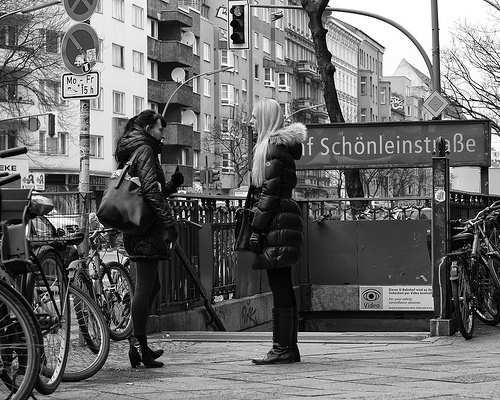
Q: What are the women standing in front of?
A: Entrance to the subway.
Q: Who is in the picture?
A: Two women.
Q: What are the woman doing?
A: Talking.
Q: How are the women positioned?
A: Across from one another.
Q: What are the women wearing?
A: Coats.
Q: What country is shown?
A: Germany.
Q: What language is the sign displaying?
A: German.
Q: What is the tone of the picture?
A: Black and white.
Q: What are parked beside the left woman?
A: Bicycles.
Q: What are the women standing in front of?
A: The subway.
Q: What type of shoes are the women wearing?
A: Boots.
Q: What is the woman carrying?
A: Shoulder bag.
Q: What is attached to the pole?
A: Traffic light.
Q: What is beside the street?
A: Building.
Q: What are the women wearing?
A: Leggings.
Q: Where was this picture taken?
A: In berlin.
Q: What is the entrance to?
A: Subway.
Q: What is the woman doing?
A: Smoking a cigarette.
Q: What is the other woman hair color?
A: Blonde.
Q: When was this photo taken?
A: During the day.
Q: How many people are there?
A: 2.